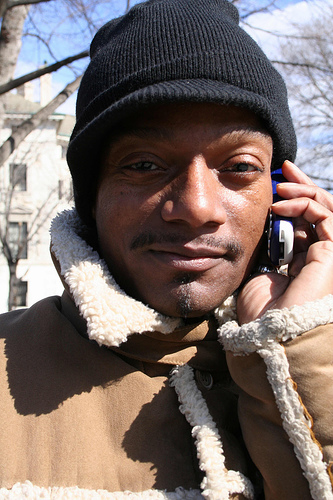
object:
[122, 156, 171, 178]
eye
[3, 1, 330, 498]
man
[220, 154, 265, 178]
eye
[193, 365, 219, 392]
button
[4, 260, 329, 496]
coat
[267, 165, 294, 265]
phone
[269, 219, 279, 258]
blue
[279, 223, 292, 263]
white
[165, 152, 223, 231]
nose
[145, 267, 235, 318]
beard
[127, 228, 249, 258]
mustache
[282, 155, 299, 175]
fingernail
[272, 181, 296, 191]
fingernail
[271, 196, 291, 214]
fingernail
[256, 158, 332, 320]
hand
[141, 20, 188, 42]
black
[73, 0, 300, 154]
cap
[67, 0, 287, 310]
head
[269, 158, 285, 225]
ear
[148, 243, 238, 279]
mouth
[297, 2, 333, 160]
trees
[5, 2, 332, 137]
background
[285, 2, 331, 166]
daytime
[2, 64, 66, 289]
building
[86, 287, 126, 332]
white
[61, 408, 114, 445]
brown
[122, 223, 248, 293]
smirk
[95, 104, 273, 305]
face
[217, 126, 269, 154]
eyebrow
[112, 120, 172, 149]
eyebrow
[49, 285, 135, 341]
collar